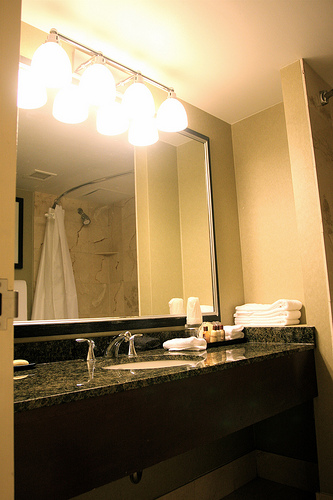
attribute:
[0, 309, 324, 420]
counter — brown, marble, black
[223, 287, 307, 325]
white — folded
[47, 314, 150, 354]
faucets — silver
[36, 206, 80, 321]
curtain — white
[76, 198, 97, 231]
shower head — hanging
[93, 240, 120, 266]
shelve — small, fitted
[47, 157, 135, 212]
rod — silver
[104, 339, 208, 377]
sink — white, round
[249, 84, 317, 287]
wall — brown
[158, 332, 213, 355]
towel — folded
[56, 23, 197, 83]
bar — silver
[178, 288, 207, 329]
stack — plastic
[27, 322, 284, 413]
counter top — black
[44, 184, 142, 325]
walls — marbelized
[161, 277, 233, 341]
cups — white